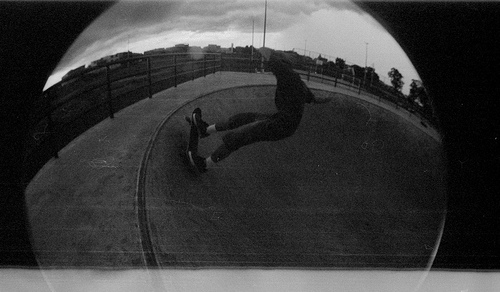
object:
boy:
[188, 51, 336, 171]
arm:
[262, 55, 269, 73]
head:
[265, 49, 296, 80]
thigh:
[237, 121, 278, 145]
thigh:
[241, 108, 269, 123]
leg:
[211, 118, 273, 165]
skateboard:
[184, 101, 209, 181]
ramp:
[139, 81, 441, 268]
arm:
[308, 94, 329, 107]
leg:
[204, 107, 274, 134]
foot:
[187, 149, 211, 174]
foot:
[188, 106, 210, 138]